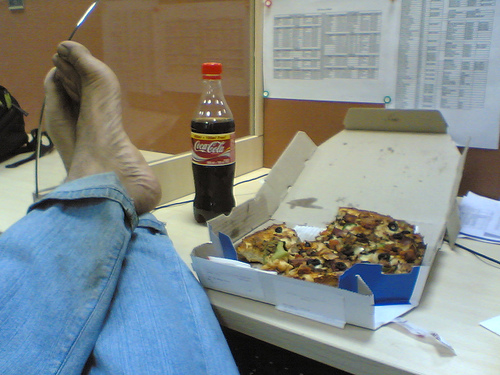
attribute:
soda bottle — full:
[190, 61, 238, 228]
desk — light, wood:
[0, 133, 498, 374]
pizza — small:
[238, 206, 426, 287]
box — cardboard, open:
[190, 107, 470, 330]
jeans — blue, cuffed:
[0, 172, 241, 375]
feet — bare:
[42, 39, 165, 215]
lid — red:
[199, 60, 222, 77]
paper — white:
[263, 0, 388, 103]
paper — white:
[388, 0, 499, 152]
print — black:
[272, 7, 381, 83]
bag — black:
[0, 82, 53, 170]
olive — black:
[334, 261, 347, 271]